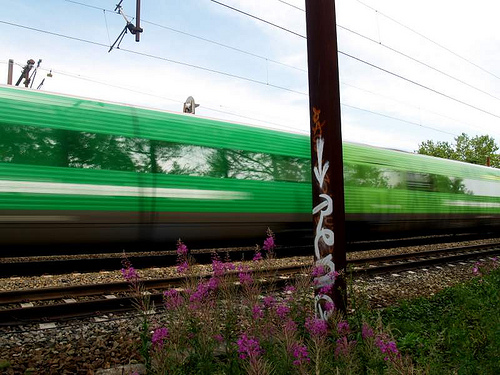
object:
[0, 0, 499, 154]
cloud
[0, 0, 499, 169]
sky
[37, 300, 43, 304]
rocks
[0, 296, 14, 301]
brown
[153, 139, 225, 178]
window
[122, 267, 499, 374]
grass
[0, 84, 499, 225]
side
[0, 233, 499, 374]
land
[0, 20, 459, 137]
power line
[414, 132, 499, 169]
trees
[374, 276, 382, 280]
rocks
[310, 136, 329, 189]
graffiti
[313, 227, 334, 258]
letter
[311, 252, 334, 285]
letter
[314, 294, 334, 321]
letter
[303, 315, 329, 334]
flower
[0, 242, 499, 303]
tracks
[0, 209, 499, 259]
shadow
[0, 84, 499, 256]
train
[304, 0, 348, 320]
pole